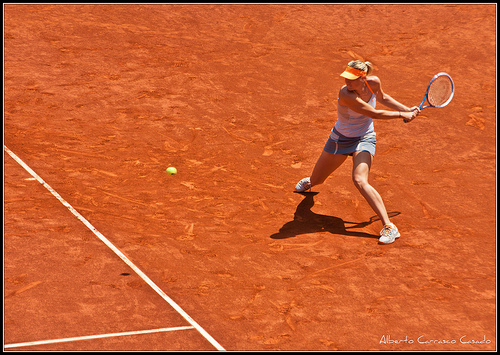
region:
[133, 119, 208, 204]
a tennis ball in the air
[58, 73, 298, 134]
a orange tennis court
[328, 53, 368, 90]
a orange visor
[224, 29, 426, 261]
a woman standing on a tenins court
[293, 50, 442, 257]
a woman wearing sneakers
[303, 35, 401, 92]
a woman wearing cap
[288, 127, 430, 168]
a woman wearing shorts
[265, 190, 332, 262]
shadow on the ground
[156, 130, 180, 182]
a ball in air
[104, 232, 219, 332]
white line in the ground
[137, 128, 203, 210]
a green ball flying in air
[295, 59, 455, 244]
young woman playing tennis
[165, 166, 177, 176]
yellow tennis ball in the air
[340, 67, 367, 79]
visor cap the woman is wearing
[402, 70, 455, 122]
tennis racket in woman's hands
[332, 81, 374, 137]
light colored top the woman is wearing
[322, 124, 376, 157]
tennis skirt woman is wearing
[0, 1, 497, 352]
orange and white tennis court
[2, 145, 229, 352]
white strip on orange tennis court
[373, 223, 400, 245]
left tennis shoe of the woman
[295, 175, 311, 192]
woman's right tennis shoe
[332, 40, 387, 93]
head of a person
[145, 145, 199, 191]
ball in mid air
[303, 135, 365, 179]
thigh of a person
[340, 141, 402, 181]
thigh of a person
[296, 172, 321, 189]
leg of a person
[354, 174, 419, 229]
leg of a person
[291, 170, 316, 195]
feet of a person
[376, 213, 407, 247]
feet of a person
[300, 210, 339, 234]
shadow of a person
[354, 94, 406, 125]
arm of a person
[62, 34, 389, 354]
the turf is orange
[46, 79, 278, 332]
the turf has footprints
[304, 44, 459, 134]
the woman is holding a tennis racquet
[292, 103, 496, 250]
the woman wears a gray skirt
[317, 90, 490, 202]
the woman has a white tank top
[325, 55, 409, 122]
the woman wears an orange visor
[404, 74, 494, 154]
the racquet has a white net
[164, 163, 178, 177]
A tennis ball on a court.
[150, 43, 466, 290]
white woman playing tennis on court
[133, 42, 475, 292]
blonde woman playing tennis on court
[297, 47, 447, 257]
tennis player wearing orange visor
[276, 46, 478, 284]
female tennis player wearing white shoes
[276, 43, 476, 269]
woman swinging tennis racket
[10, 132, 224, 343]
white lines of tennis court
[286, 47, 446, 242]
a woman playing tennis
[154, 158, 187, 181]
tennis ball being served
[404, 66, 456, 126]
tennis racket in the woman's hands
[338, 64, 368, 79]
orange visor on the woman's head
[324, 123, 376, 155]
gray and orange colored skort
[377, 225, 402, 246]
white and orange tennis shoes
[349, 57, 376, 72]
woman's hair pulled into a pony tail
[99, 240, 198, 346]
white lines on a tennis court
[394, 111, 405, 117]
bracelet on the woman's right wrist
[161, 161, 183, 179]
yellow colored tennis ball in air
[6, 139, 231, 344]
white colored line on tennis court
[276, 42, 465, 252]
tennis player holding a racket about to hit the ball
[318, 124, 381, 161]
grey colored shorts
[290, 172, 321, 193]
right shoe of tennis player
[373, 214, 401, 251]
left shoe of tennis player